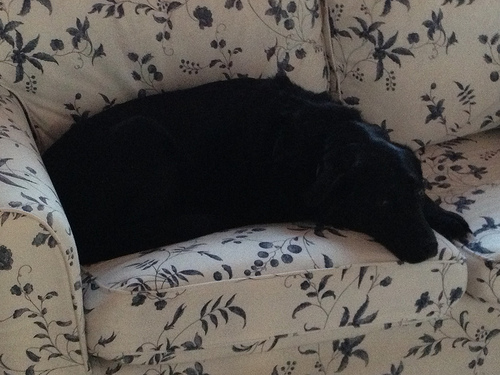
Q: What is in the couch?
A: Dog.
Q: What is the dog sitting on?
A: Couch.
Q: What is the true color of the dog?
A: Black.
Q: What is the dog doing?
A: Sleeping.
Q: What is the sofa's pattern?
A: Flower.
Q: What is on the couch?
A: Dog.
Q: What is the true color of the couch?
A: White.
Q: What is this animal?
A: Dog.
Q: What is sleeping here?
A: Dog.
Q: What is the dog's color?
A: Black.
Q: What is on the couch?
A: A dog.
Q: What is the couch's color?
A: White.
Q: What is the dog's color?
A: Black.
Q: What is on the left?
A: Armrest.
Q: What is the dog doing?
A: Lying.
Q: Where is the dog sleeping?
A: The couch.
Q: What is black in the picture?
A: A dog.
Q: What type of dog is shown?
A: Labrador.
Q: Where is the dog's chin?
A: On the couch.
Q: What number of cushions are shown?
A: 4.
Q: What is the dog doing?
A: Resting.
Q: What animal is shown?
A: A dog.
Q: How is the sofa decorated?
A: Leaf and flower pattern.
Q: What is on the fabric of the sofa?
A: Leaves and flowers.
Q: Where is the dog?
A: Sofa.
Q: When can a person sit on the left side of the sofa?
A: After the dog moves.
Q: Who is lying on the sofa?
A: Dog.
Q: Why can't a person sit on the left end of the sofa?
A: Dog is there.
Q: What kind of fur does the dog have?
A: Short and black.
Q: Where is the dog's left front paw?
A: Stretched out.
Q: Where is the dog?
A: On the couch.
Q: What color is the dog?
A: Black.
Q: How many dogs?
A: 1.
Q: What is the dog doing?
A: Resting.